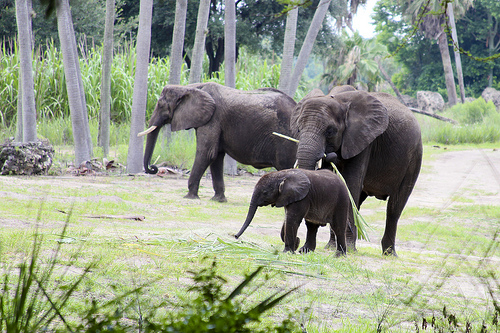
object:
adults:
[134, 81, 297, 203]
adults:
[278, 84, 424, 259]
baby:
[231, 167, 351, 259]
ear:
[339, 93, 390, 161]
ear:
[168, 89, 216, 135]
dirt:
[405, 149, 499, 207]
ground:
[0, 142, 498, 333]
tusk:
[135, 125, 157, 138]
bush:
[224, 264, 264, 303]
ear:
[270, 169, 315, 208]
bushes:
[0, 31, 311, 125]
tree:
[128, 0, 154, 174]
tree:
[97, 0, 118, 168]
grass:
[0, 96, 499, 332]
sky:
[329, 0, 403, 38]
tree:
[50, 0, 91, 172]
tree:
[219, 0, 237, 175]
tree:
[189, 0, 213, 85]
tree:
[445, 1, 467, 103]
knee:
[279, 222, 289, 243]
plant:
[270, 130, 375, 243]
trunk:
[233, 205, 257, 239]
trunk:
[297, 135, 324, 169]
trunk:
[141, 122, 158, 176]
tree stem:
[128, 0, 153, 178]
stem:
[124, 0, 155, 176]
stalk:
[270, 130, 347, 193]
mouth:
[293, 138, 329, 159]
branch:
[412, 318, 420, 332]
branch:
[439, 303, 449, 319]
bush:
[478, 317, 486, 333]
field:
[0, 141, 498, 332]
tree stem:
[278, 4, 298, 95]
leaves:
[0, 172, 499, 333]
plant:
[0, 176, 498, 332]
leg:
[185, 126, 221, 192]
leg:
[380, 197, 417, 254]